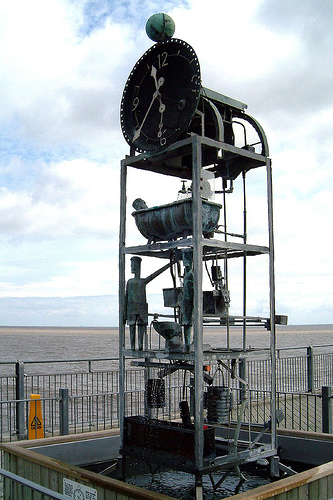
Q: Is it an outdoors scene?
A: Yes, it is outdoors.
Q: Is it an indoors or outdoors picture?
A: It is outdoors.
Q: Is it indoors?
A: No, it is outdoors.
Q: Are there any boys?
A: No, there are no boys.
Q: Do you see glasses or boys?
A: No, there are no boys or glasses.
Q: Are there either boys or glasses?
A: No, there are no boys or glasses.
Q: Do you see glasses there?
A: No, there are no glasses.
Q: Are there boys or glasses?
A: No, there are no glasses or boys.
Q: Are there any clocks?
A: Yes, there is a clock.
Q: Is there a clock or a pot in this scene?
A: Yes, there is a clock.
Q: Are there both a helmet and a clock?
A: No, there is a clock but no helmets.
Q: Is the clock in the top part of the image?
A: Yes, the clock is in the top of the image.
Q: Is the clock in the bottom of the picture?
A: No, the clock is in the top of the image.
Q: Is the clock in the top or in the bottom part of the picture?
A: The clock is in the top of the image.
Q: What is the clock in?
A: The clock is in the tower.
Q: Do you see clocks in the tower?
A: Yes, there is a clock in the tower.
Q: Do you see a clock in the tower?
A: Yes, there is a clock in the tower.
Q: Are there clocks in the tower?
A: Yes, there is a clock in the tower.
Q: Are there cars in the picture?
A: No, there are no cars.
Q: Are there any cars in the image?
A: No, there are no cars.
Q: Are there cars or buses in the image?
A: No, there are no cars or buses.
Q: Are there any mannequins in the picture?
A: No, there are no mannequins.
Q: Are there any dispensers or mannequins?
A: No, there are no mannequins or dispensers.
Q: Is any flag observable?
A: No, there are no flags.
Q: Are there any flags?
A: No, there are no flags.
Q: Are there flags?
A: No, there are no flags.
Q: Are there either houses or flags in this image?
A: No, there are no flags or houses.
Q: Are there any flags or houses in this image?
A: No, there are no flags or houses.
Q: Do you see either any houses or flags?
A: No, there are no flags or houses.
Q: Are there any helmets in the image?
A: No, there are no helmets.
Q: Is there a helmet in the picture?
A: No, there are no helmets.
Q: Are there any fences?
A: Yes, there is a fence.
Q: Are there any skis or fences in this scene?
A: Yes, there is a fence.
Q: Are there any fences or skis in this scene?
A: Yes, there is a fence.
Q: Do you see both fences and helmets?
A: No, there is a fence but no helmets.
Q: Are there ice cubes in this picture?
A: No, there are no ice cubes.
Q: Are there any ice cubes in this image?
A: No, there are no ice cubes.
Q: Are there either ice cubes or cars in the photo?
A: No, there are no ice cubes or cars.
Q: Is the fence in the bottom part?
A: Yes, the fence is in the bottom of the image.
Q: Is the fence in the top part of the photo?
A: No, the fence is in the bottom of the image.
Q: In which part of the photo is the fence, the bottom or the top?
A: The fence is in the bottom of the image.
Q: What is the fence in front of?
A: The fence is in front of the water.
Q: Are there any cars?
A: No, there are no cars.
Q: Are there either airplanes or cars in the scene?
A: No, there are no cars or airplanes.